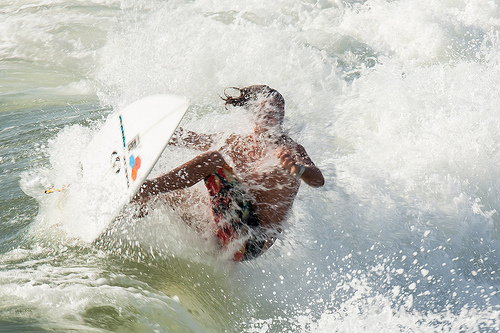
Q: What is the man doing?
A: Surfing.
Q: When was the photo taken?
A: Day time.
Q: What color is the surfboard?
A: White.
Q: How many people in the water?
A: One.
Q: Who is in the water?
A: A man.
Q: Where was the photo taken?
A: The ocean.